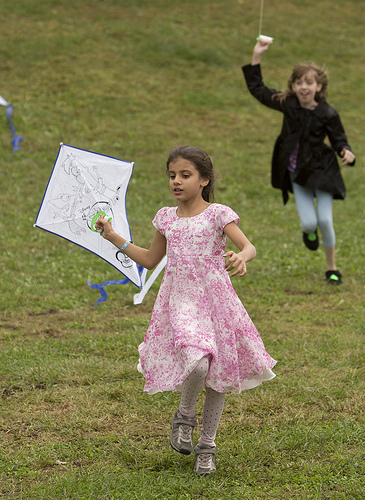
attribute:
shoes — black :
[300, 227, 341, 283]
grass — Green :
[251, 221, 363, 336]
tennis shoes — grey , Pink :
[167, 407, 197, 451]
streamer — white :
[141, 252, 168, 308]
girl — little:
[95, 145, 276, 475]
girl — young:
[240, 34, 356, 286]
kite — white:
[32, 140, 167, 306]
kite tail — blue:
[84, 273, 130, 304]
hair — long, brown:
[269, 62, 330, 109]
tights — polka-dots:
[180, 349, 221, 441]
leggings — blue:
[291, 173, 338, 246]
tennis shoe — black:
[302, 230, 319, 250]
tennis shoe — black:
[326, 267, 341, 283]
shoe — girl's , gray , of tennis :
[167, 410, 193, 455]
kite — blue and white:
[27, 127, 155, 295]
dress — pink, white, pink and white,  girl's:
[135, 202, 278, 395]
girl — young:
[72, 96, 265, 421]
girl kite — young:
[32, 141, 280, 476]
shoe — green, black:
[289, 229, 352, 310]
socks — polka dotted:
[174, 350, 229, 469]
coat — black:
[242, 61, 354, 197]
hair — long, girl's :
[166, 145, 213, 204]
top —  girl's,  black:
[251, 54, 363, 208]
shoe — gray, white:
[166, 410, 195, 457]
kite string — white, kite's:
[260, 0, 263, 35]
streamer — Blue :
[78, 255, 144, 310]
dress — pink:
[147, 207, 284, 395]